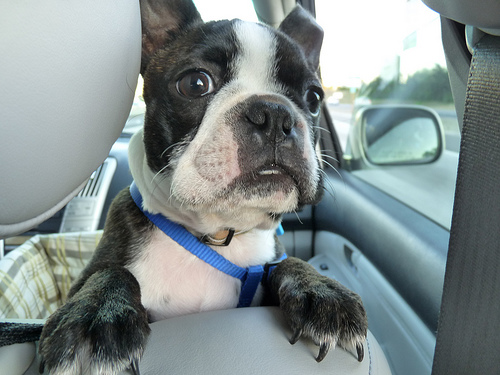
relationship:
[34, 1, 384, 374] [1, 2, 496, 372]
dog in vehicle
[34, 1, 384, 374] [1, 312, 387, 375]
dog on seat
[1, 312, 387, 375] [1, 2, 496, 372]
seat in vehicle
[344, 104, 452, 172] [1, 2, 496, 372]
mirror on car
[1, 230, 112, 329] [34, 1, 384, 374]
basket behind dog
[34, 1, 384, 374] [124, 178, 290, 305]
dog has leash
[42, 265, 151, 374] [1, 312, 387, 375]
paws are on seat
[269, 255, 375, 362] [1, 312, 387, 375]
paws are on seat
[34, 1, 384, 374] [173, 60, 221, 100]
dog has an eye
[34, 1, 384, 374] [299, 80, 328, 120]
dog has an eye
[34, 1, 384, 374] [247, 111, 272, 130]
dog has a nostril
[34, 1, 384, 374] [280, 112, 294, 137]
dog has a nostril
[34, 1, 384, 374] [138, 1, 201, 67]
dog has an ear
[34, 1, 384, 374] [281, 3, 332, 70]
dog has an ear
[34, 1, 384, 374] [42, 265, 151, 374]
dog has a leg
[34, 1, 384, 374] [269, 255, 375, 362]
dog has a leg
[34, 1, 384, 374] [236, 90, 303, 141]
dog has a nose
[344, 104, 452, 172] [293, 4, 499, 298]
mirror on side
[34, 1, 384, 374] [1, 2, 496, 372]
dog in car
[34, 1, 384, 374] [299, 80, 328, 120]
dog has a right eye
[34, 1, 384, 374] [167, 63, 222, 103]
dog has a eye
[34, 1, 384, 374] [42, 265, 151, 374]
dog has paws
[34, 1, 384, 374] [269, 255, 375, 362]
dog has a paw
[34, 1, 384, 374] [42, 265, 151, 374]
dog has a paw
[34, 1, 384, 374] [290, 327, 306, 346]
dog has a claw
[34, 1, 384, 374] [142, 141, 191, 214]
dog has whiskers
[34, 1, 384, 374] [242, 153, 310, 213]
dog has a mouth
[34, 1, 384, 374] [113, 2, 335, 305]
dog has a head